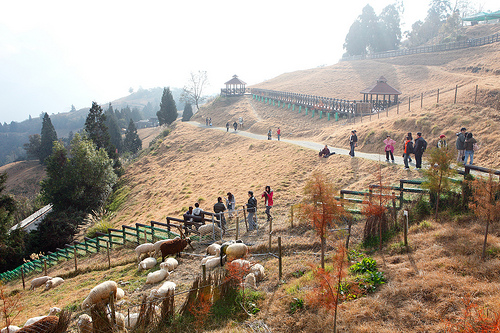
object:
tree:
[181, 101, 196, 121]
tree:
[153, 85, 178, 127]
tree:
[121, 117, 142, 155]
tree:
[37, 111, 57, 167]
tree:
[341, 19, 371, 56]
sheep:
[134, 256, 158, 269]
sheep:
[159, 236, 193, 262]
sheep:
[33, 273, 52, 287]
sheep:
[145, 260, 172, 283]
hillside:
[0, 11, 500, 332]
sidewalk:
[175, 115, 498, 180]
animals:
[224, 241, 248, 261]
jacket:
[245, 196, 259, 216]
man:
[241, 189, 257, 231]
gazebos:
[357, 73, 402, 117]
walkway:
[245, 88, 369, 117]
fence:
[0, 210, 228, 282]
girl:
[260, 183, 275, 224]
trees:
[40, 131, 117, 217]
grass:
[0, 123, 500, 333]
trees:
[288, 165, 357, 300]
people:
[382, 134, 398, 162]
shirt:
[261, 190, 275, 207]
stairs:
[166, 229, 181, 237]